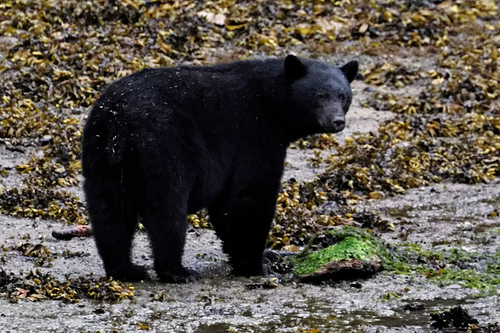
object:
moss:
[291, 226, 408, 276]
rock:
[289, 231, 385, 283]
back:
[82, 55, 359, 285]